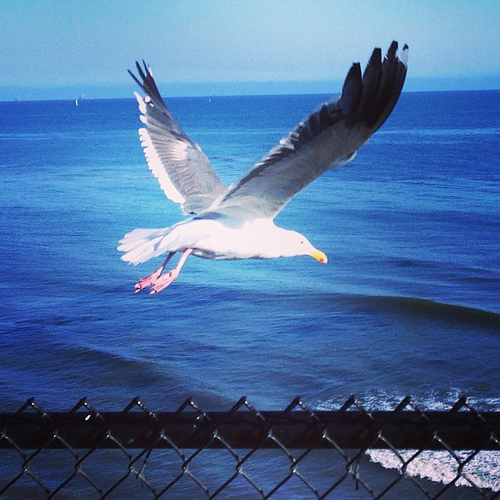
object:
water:
[0, 88, 497, 499]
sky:
[3, 1, 28, 87]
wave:
[428, 301, 496, 324]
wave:
[72, 331, 206, 404]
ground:
[461, 152, 479, 174]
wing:
[125, 55, 225, 215]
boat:
[73, 94, 91, 107]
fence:
[0, 393, 499, 498]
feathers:
[116, 226, 167, 266]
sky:
[190, 4, 216, 79]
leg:
[132, 250, 178, 295]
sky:
[302, 24, 357, 50]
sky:
[0, 1, 499, 103]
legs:
[149, 248, 194, 296]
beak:
[310, 247, 329, 264]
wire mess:
[50, 395, 88, 441]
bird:
[117, 39, 410, 296]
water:
[3, 182, 47, 500]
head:
[275, 229, 329, 264]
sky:
[81, 2, 92, 75]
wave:
[449, 302, 497, 318]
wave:
[382, 198, 485, 223]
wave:
[420, 252, 493, 281]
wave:
[56, 340, 148, 380]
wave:
[417, 125, 470, 141]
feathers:
[211, 229, 279, 256]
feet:
[148, 266, 183, 295]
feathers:
[213, 38, 410, 220]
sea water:
[24, 138, 111, 239]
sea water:
[376, 177, 453, 294]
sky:
[423, 2, 486, 66]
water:
[367, 182, 498, 277]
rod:
[0, 409, 182, 444]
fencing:
[173, 420, 429, 496]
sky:
[39, 11, 47, 69]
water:
[151, 377, 368, 393]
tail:
[115, 226, 168, 267]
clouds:
[162, 22, 304, 70]